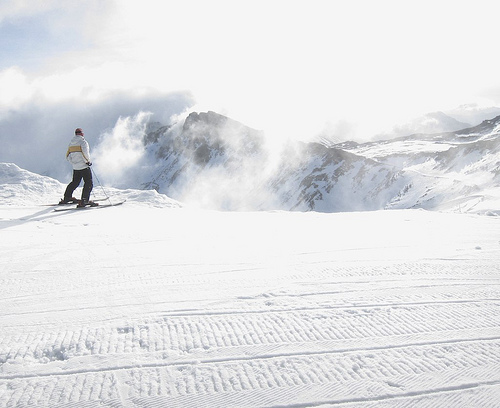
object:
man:
[64, 127, 99, 206]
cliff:
[133, 178, 253, 270]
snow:
[164, 226, 342, 323]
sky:
[38, 15, 112, 96]